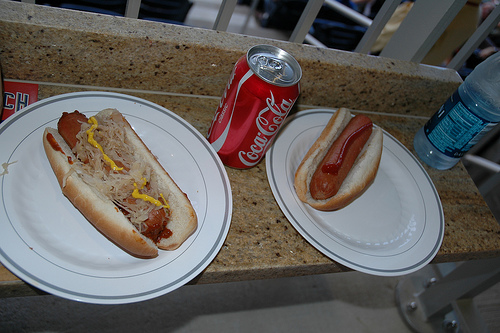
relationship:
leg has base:
[419, 257, 498, 320] [395, 263, 462, 333]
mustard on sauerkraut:
[86, 116, 124, 173] [62, 111, 170, 232]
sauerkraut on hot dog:
[62, 111, 170, 232] [58, 110, 168, 238]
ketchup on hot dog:
[320, 121, 375, 175] [310, 114, 372, 200]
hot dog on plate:
[58, 110, 168, 238] [0, 91, 235, 304]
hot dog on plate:
[310, 114, 372, 200] [265, 107, 446, 279]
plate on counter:
[0, 91, 235, 304] [0, 1, 499, 299]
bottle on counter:
[412, 50, 498, 170] [0, 1, 499, 299]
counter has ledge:
[0, 1, 499, 299] [1, 0, 466, 117]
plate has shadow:
[0, 91, 235, 304] [114, 317, 194, 332]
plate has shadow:
[265, 107, 446, 279] [338, 282, 426, 309]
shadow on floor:
[114, 317, 194, 332] [0, 258, 499, 332]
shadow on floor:
[338, 282, 426, 309] [0, 258, 499, 332]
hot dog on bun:
[58, 110, 168, 238] [43, 108, 200, 257]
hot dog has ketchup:
[310, 114, 372, 200] [320, 121, 375, 175]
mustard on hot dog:
[86, 116, 124, 173] [58, 110, 168, 238]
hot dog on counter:
[58, 110, 168, 238] [0, 1, 499, 299]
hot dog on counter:
[310, 114, 372, 200] [0, 1, 499, 299]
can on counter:
[204, 44, 302, 170] [0, 1, 499, 299]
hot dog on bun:
[310, 114, 372, 200] [295, 107, 383, 212]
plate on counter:
[265, 107, 446, 279] [0, 1, 499, 299]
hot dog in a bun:
[58, 110, 168, 238] [43, 108, 200, 257]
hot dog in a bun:
[310, 114, 372, 200] [295, 107, 383, 212]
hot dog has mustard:
[58, 110, 168, 238] [86, 116, 124, 173]